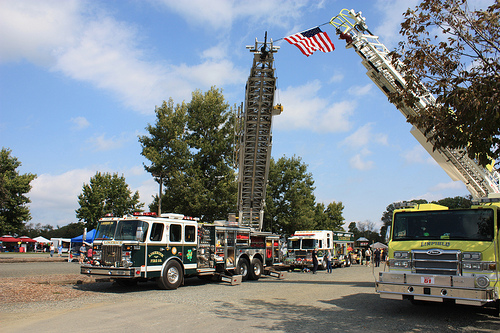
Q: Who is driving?
A: Man.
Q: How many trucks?
A: Two.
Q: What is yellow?
A: Truck.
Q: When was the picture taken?
A: Daytime.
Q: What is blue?
A: Sky.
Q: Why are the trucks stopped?
A: Ladder is up.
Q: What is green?
A: Trees.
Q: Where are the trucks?
A: On the road.